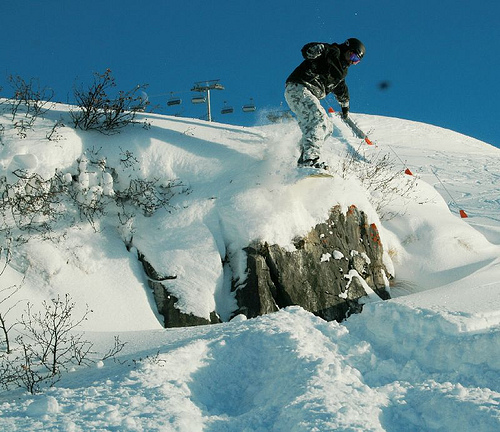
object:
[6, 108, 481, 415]
ground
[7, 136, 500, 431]
snow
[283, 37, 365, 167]
man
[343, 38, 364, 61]
helmet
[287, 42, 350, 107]
jacket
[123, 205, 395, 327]
rock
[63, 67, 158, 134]
bushes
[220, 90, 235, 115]
ski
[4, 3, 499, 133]
top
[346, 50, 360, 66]
goggles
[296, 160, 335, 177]
snowboard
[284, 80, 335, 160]
snowpants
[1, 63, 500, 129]
distance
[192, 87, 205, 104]
chair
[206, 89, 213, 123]
pole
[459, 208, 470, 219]
flag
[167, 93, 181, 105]
empty